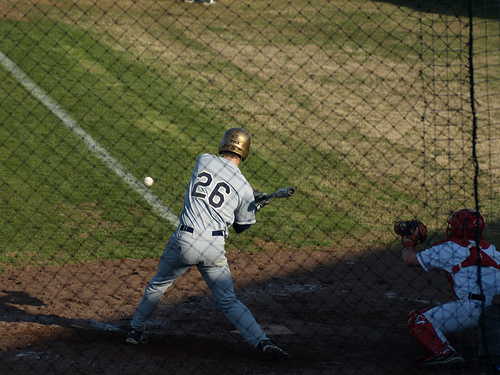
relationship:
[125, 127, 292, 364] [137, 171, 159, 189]
ball player readies to hit ball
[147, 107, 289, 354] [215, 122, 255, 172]
neck of man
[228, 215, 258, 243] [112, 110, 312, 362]
elbow of man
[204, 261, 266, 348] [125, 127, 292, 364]
leg of ball player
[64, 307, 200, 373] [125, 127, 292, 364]
foot of ball player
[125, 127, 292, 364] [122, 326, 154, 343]
ball player wearing shoes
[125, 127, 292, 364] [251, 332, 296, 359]
ball player wearing shoes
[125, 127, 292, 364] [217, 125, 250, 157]
ball player wearing helmet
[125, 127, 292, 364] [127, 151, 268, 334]
ball player wearing uniform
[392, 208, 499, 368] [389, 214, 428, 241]
catcher wearing glove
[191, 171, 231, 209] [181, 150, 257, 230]
number on jersey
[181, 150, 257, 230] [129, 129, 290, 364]
jersey of ball player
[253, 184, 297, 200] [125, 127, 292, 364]
bat of ball player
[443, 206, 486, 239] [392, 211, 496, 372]
catcher's mask of catcher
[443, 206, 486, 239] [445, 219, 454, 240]
catcher's mask protects face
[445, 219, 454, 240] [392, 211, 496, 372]
face of catcher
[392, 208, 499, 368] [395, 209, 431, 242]
catcher wears glove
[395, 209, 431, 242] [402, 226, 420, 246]
glove on hand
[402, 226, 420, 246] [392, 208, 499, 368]
hand of catcher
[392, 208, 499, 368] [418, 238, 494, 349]
catcher wearing white (clothes)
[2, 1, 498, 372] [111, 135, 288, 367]
netting behind batter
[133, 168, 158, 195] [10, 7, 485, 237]
ball in air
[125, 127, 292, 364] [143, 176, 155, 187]
ball player playing ball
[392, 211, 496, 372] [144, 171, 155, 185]
catcher readies to catch pitch